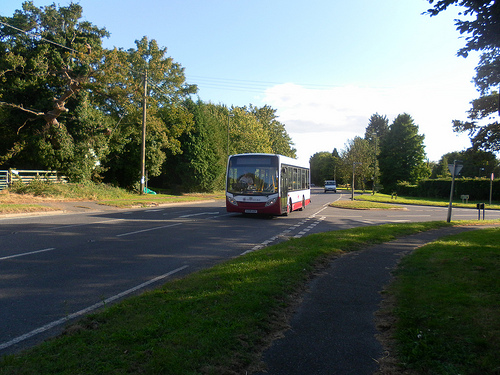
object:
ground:
[0, 185, 500, 337]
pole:
[136, 50, 154, 192]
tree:
[380, 114, 427, 198]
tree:
[0, 0, 112, 190]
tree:
[187, 99, 223, 193]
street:
[314, 204, 498, 233]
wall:
[351, 128, 401, 202]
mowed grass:
[384, 228, 499, 370]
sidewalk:
[249, 219, 498, 374]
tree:
[364, 114, 391, 195]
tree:
[341, 136, 367, 202]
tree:
[430, 1, 499, 156]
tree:
[329, 149, 340, 179]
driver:
[261, 174, 277, 193]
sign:
[477, 203, 488, 222]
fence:
[1, 170, 68, 188]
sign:
[443, 156, 469, 224]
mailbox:
[475, 173, 498, 219]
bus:
[227, 154, 311, 216]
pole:
[445, 162, 462, 223]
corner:
[313, 209, 484, 231]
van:
[323, 180, 337, 193]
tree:
[125, 41, 185, 184]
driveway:
[0, 193, 339, 347]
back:
[444, 161, 464, 179]